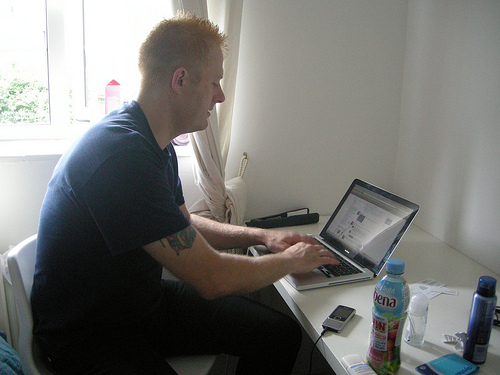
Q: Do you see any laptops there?
A: Yes, there is a laptop.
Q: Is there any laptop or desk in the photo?
A: Yes, there is a laptop.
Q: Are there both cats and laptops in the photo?
A: No, there is a laptop but no cats.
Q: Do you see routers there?
A: No, there are no routers.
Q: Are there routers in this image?
A: No, there are no routers.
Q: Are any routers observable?
A: No, there are no routers.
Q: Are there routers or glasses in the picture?
A: No, there are no routers or glasses.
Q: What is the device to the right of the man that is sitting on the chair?
A: The device is a laptop.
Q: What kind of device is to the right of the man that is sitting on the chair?
A: The device is a laptop.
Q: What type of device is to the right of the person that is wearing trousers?
A: The device is a laptop.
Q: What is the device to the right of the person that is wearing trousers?
A: The device is a laptop.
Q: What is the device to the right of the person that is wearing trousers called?
A: The device is a laptop.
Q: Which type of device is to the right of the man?
A: The device is a laptop.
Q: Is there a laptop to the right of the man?
A: Yes, there is a laptop to the right of the man.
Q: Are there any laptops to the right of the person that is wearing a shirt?
A: Yes, there is a laptop to the right of the man.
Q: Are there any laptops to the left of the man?
A: No, the laptop is to the right of the man.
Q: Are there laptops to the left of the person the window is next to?
A: No, the laptop is to the right of the man.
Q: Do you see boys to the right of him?
A: No, there is a laptop to the right of the man.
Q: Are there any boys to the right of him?
A: No, there is a laptop to the right of the man.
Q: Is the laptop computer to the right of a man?
A: Yes, the laptop computer is to the right of a man.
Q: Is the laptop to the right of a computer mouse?
A: No, the laptop is to the right of a man.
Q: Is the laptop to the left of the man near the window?
A: No, the laptop is to the right of the man.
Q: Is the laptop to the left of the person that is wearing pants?
A: No, the laptop is to the right of the man.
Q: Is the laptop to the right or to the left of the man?
A: The laptop is to the right of the man.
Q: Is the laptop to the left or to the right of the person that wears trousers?
A: The laptop is to the right of the man.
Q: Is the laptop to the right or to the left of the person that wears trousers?
A: The laptop is to the right of the man.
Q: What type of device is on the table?
A: The device is a laptop.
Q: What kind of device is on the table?
A: The device is a laptop.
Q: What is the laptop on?
A: The laptop is on the table.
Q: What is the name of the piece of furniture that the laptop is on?
A: The piece of furniture is a table.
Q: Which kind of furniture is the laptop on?
A: The laptop is on the table.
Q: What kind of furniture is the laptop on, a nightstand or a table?
A: The laptop is on a table.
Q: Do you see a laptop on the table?
A: Yes, there is a laptop on the table.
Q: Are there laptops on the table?
A: Yes, there is a laptop on the table.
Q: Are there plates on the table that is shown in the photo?
A: No, there is a laptop on the table.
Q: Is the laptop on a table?
A: Yes, the laptop is on a table.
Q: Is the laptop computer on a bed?
A: No, the laptop computer is on a table.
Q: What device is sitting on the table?
A: The device is a laptop.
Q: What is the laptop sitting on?
A: The laptop computer is sitting on the table.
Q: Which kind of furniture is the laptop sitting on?
A: The laptop is sitting on the table.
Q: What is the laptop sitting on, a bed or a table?
A: The laptop is sitting on a table.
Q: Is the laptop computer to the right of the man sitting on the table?
A: Yes, the laptop computer is sitting on the table.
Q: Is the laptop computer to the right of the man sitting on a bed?
A: No, the laptop computer is sitting on the table.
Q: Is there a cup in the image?
A: No, there are no cups.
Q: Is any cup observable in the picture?
A: No, there are no cups.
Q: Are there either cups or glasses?
A: No, there are no cups or glasses.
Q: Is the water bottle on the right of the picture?
A: Yes, the water bottle is on the right of the image.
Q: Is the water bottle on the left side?
A: No, the water bottle is on the right of the image.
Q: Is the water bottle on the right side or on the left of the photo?
A: The water bottle is on the right of the image.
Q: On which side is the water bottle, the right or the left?
A: The water bottle is on the right of the image.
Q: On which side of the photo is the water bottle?
A: The water bottle is on the right of the image.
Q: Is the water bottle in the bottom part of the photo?
A: Yes, the water bottle is in the bottom of the image.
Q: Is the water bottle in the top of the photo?
A: No, the water bottle is in the bottom of the image.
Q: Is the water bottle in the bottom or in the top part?
A: The water bottle is in the bottom of the image.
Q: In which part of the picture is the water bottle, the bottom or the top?
A: The water bottle is in the bottom of the image.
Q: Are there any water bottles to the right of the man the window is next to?
A: Yes, there is a water bottle to the right of the man.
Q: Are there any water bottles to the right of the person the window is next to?
A: Yes, there is a water bottle to the right of the man.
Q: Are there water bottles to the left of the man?
A: No, the water bottle is to the right of the man.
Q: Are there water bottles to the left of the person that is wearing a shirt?
A: No, the water bottle is to the right of the man.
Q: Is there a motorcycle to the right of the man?
A: No, there is a water bottle to the right of the man.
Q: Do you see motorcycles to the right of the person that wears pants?
A: No, there is a water bottle to the right of the man.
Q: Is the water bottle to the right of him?
A: Yes, the water bottle is to the right of a man.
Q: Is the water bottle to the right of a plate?
A: No, the water bottle is to the right of a man.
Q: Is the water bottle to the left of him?
A: No, the water bottle is to the right of the man.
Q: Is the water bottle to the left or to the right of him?
A: The water bottle is to the right of the man.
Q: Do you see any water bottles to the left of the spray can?
A: Yes, there is a water bottle to the left of the spray can.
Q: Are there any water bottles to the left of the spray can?
A: Yes, there is a water bottle to the left of the spray can.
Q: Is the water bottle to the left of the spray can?
A: Yes, the water bottle is to the left of the spray can.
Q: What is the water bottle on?
A: The water bottle is on the table.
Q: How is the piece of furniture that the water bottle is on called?
A: The piece of furniture is a table.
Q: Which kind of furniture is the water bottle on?
A: The water bottle is on the table.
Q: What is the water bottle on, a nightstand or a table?
A: The water bottle is on a table.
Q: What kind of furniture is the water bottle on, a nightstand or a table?
A: The water bottle is on a table.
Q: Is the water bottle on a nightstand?
A: No, the water bottle is on the table.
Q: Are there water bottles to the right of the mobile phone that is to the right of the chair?
A: Yes, there is a water bottle to the right of the cellphone.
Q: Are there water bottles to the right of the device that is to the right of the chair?
A: Yes, there is a water bottle to the right of the cellphone.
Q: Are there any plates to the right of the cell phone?
A: No, there is a water bottle to the right of the cell phone.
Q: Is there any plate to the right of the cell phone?
A: No, there is a water bottle to the right of the cell phone.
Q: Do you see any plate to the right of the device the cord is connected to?
A: No, there is a water bottle to the right of the cell phone.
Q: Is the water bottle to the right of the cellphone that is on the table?
A: Yes, the water bottle is to the right of the cell phone.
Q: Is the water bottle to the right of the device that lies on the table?
A: Yes, the water bottle is to the right of the cell phone.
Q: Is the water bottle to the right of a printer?
A: No, the water bottle is to the right of the cell phone.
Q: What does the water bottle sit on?
A: The water bottle sits on the table.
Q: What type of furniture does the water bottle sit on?
A: The water bottle sits on the table.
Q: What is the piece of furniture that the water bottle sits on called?
A: The piece of furniture is a table.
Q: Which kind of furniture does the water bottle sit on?
A: The water bottle sits on the table.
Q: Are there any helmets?
A: No, there are no helmets.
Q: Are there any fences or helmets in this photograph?
A: No, there are no helmets or fences.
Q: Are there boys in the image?
A: No, there are no boys.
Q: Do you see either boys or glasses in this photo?
A: No, there are no boys or glasses.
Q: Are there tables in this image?
A: Yes, there is a table.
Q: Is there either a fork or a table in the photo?
A: Yes, there is a table.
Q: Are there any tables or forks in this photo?
A: Yes, there is a table.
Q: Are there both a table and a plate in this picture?
A: No, there is a table but no plates.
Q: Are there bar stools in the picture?
A: No, there are no bar stools.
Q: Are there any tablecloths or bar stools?
A: No, there are no bar stools or tablecloths.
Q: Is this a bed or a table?
A: This is a table.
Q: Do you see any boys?
A: No, there are no boys.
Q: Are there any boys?
A: No, there are no boys.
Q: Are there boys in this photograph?
A: No, there are no boys.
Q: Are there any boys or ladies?
A: No, there are no boys or ladies.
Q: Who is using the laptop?
A: The man is using the laptop.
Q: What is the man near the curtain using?
A: The man is using a laptop.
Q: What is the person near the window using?
A: The man is using a laptop.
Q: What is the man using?
A: The man is using a laptop.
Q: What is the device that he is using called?
A: The device is a laptop.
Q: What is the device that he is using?
A: The device is a laptop.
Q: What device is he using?
A: The man is using a laptop.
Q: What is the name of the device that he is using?
A: The device is a laptop.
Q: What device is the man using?
A: The man is using a laptop.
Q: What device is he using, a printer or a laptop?
A: The man is using a laptop.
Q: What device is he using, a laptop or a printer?
A: The man is using a laptop.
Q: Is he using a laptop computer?
A: Yes, the man is using a laptop computer.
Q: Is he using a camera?
A: No, the man is using a laptop computer.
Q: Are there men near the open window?
A: Yes, there is a man near the window.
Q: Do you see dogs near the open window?
A: No, there is a man near the window.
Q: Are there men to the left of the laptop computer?
A: Yes, there is a man to the left of the laptop computer.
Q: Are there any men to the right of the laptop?
A: No, the man is to the left of the laptop.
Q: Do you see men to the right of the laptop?
A: No, the man is to the left of the laptop.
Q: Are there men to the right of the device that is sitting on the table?
A: No, the man is to the left of the laptop.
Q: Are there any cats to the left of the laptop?
A: No, there is a man to the left of the laptop.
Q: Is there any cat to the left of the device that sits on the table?
A: No, there is a man to the left of the laptop.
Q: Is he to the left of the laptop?
A: Yes, the man is to the left of the laptop.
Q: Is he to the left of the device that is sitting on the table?
A: Yes, the man is to the left of the laptop.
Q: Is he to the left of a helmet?
A: No, the man is to the left of the laptop.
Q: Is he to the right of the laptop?
A: No, the man is to the left of the laptop.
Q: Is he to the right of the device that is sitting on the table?
A: No, the man is to the left of the laptop.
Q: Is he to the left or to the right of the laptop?
A: The man is to the left of the laptop.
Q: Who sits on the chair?
A: The man sits on the chair.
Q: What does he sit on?
A: The man sits on the chair.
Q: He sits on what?
A: The man sits on the chair.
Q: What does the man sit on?
A: The man sits on the chair.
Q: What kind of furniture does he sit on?
A: The man sits on the chair.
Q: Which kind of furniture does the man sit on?
A: The man sits on the chair.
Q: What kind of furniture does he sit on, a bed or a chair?
A: The man sits on a chair.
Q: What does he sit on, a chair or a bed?
A: The man sits on a chair.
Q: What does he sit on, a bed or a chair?
A: The man sits on a chair.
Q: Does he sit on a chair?
A: Yes, the man sits on a chair.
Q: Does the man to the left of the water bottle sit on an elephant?
A: No, the man sits on a chair.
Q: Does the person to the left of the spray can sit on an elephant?
A: No, the man sits on a chair.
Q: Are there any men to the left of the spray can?
A: Yes, there is a man to the left of the spray can.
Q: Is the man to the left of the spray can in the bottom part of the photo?
A: Yes, the man is to the left of the spray can.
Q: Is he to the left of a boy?
A: No, the man is to the left of the spray can.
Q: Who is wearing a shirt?
A: The man is wearing a shirt.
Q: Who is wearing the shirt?
A: The man is wearing a shirt.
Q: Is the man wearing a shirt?
A: Yes, the man is wearing a shirt.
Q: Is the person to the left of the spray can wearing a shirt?
A: Yes, the man is wearing a shirt.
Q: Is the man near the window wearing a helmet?
A: No, the man is wearing a shirt.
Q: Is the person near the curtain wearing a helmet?
A: No, the man is wearing a shirt.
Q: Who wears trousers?
A: The man wears trousers.